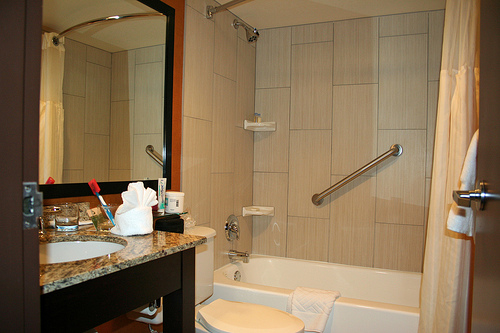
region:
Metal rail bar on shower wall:
[308, 141, 408, 210]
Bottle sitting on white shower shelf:
[247, 108, 263, 122]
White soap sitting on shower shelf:
[247, 201, 261, 211]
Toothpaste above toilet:
[154, 172, 169, 216]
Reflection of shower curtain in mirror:
[41, 28, 68, 180]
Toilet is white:
[135, 222, 303, 332]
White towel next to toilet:
[283, 284, 338, 331]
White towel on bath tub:
[282, 284, 341, 331]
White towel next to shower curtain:
[440, 125, 479, 237]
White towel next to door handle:
[438, 124, 478, 235]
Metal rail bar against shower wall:
[302, 135, 408, 205]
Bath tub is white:
[209, 248, 423, 331]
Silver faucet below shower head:
[219, 209, 255, 261]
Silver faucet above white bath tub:
[222, 215, 250, 262]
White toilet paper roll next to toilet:
[132, 295, 158, 313]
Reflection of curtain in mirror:
[40, 32, 69, 178]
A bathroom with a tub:
[1, 2, 497, 329]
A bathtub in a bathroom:
[212, 201, 432, 317]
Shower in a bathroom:
[195, 20, 449, 306]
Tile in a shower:
[283, 53, 362, 180]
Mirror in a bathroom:
[43, 4, 195, 207]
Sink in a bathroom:
[31, 199, 213, 319]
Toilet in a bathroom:
[171, 226, 305, 331]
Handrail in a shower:
[296, 108, 420, 227]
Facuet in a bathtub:
[213, 202, 263, 275]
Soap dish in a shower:
[245, 196, 274, 220]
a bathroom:
[24, 10, 482, 331]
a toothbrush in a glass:
[92, 171, 118, 216]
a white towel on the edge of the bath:
[283, 272, 346, 327]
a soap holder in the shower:
[242, 102, 286, 151]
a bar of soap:
[245, 203, 264, 218]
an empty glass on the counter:
[53, 201, 83, 232]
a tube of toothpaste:
[154, 175, 169, 214]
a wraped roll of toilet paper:
[165, 186, 193, 212]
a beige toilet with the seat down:
[188, 225, 305, 330]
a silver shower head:
[228, 12, 278, 60]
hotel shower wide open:
[210, 8, 440, 318]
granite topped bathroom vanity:
[31, 218, 205, 318]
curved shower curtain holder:
[44, 16, 154, 42]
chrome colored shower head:
[227, 18, 289, 55]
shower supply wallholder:
[236, 100, 286, 147]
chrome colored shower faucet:
[218, 216, 247, 289]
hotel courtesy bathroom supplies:
[111, 183, 165, 232]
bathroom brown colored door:
[465, 25, 497, 308]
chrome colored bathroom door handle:
[454, 173, 487, 227]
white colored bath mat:
[276, 272, 351, 332]